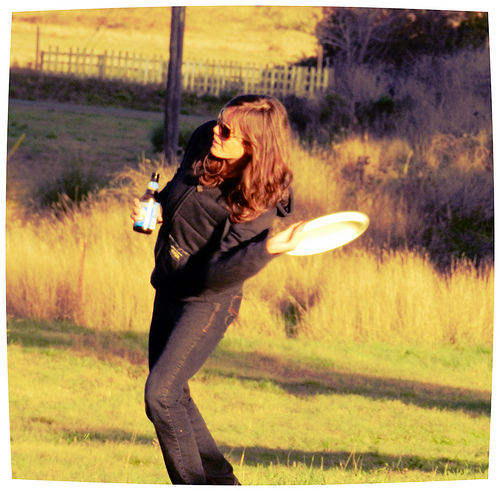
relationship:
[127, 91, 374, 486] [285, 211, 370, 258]
woman throwing a frisbee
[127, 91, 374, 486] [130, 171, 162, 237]
woman with a beer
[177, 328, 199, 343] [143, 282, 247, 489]
dark wash blue jeans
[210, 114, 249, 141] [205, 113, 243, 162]
sunglasses on her face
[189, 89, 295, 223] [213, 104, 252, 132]
hair with bangs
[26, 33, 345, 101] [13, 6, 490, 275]
fence in background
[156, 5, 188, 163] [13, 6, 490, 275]
pole in background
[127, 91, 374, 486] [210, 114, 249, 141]
woman wearing sunglasses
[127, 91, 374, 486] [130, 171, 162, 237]
woman holding bottle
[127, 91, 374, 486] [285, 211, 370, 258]
woman holding frisbee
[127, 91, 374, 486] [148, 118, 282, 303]
woman wearing a jacket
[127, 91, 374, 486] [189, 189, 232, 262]
woman wearing black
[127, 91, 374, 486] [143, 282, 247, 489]
woman wearing jeans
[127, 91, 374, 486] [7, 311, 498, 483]
woman standing on grass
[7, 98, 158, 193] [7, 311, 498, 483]
patch of green grass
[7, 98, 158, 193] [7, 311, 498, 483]
patch of grass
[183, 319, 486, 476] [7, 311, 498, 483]
patch of grass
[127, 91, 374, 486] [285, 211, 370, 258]
woman playing frisbee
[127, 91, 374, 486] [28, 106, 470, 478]
woman playing in a field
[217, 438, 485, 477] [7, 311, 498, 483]
shadow in grass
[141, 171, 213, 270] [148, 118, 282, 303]
zipped hooded jacket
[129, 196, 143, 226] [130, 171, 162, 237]
fingers on a bottle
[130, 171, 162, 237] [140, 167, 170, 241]
bottle of beer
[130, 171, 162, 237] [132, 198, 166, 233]
bottle with label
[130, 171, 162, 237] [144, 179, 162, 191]
bottle with label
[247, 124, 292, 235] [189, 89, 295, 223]
long brown hair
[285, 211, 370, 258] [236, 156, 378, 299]
frisbee to be thrown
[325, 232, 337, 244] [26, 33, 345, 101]
white picket fence